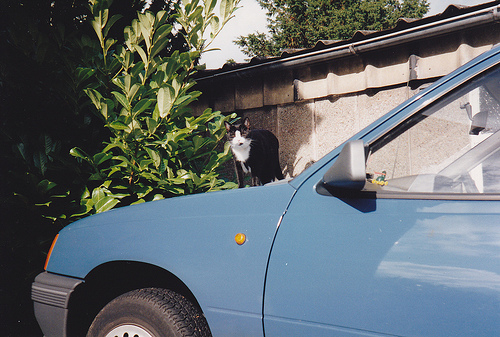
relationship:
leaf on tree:
[157, 82, 177, 121] [69, 0, 248, 219]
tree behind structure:
[233, 1, 433, 63] [182, 0, 500, 188]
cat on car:
[224, 118, 288, 189] [30, 42, 499, 336]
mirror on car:
[320, 137, 366, 192] [30, 42, 499, 336]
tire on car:
[82, 285, 212, 336] [30, 42, 499, 336]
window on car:
[366, 60, 500, 195] [30, 42, 499, 336]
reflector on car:
[234, 230, 248, 244] [30, 42, 499, 336]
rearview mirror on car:
[320, 137, 366, 192] [30, 42, 499, 336]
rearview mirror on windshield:
[459, 102, 490, 137] [367, 66, 500, 183]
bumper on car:
[30, 270, 85, 336] [30, 42, 499, 336]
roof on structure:
[187, 0, 499, 82] [182, 0, 500, 188]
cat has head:
[224, 118, 288, 189] [223, 117, 253, 148]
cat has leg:
[224, 118, 288, 189] [233, 157, 247, 189]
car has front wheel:
[30, 42, 499, 336] [82, 285, 212, 336]